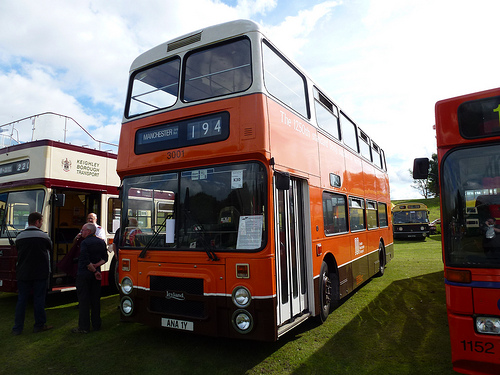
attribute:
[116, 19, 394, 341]
bus — orange, double decker, white, parked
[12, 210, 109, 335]
people — talking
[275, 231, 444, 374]
grass — green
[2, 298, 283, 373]
grass — green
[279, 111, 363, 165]
lettering — white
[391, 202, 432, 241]
bus — yellow, black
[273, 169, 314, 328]
door — white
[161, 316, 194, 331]
license plate — white, black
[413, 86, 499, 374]
bus — red, parked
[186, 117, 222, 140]
number — white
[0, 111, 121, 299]
bus — white, red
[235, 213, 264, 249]
paper — white